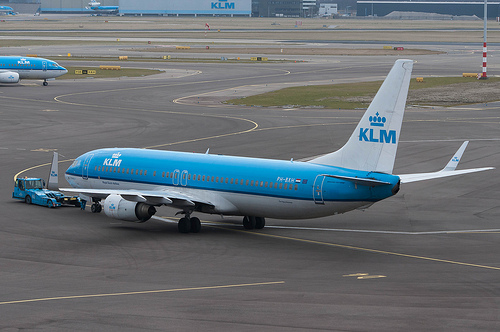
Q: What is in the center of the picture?
A: An airplane.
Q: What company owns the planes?
A: KLM.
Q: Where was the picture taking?
A: On an airport runway.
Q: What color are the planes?
A: Blue and white.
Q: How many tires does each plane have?
A: Three.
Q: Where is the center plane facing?
A: The left.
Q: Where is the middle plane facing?
A: The right.